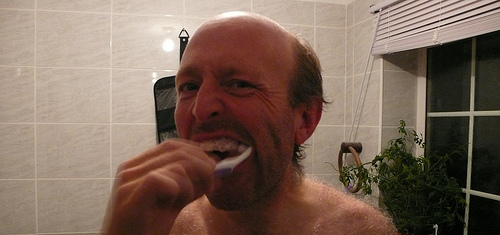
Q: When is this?
A: Night time.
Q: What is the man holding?
A: Toothbrush.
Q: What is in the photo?
A: Window.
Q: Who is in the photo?
A: A man.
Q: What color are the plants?
A: Green.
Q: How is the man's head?
A: Bald.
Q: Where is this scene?
A: In a bathroom.